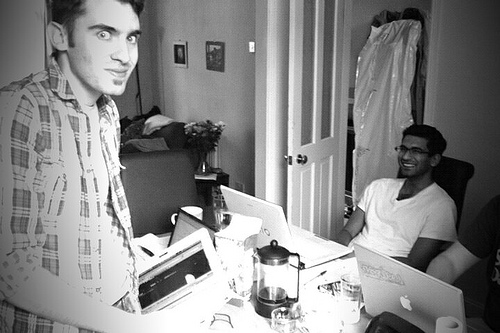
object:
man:
[0, 0, 184, 333]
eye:
[97, 30, 112, 40]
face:
[66, 0, 141, 97]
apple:
[399, 294, 412, 312]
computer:
[353, 242, 466, 333]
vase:
[196, 159, 212, 176]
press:
[132, 228, 224, 314]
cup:
[340, 273, 363, 324]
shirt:
[347, 177, 458, 258]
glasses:
[394, 146, 430, 155]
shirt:
[0, 59, 136, 333]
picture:
[205, 41, 224, 73]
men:
[333, 124, 461, 274]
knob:
[296, 154, 307, 166]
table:
[92, 230, 351, 332]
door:
[287, 0, 356, 240]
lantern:
[253, 239, 304, 318]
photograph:
[171, 41, 188, 69]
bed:
[119, 150, 210, 239]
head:
[43, 1, 164, 96]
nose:
[111, 43, 131, 64]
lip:
[104, 68, 128, 78]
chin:
[85, 76, 128, 96]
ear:
[47, 21, 69, 51]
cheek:
[69, 35, 111, 86]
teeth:
[403, 163, 415, 167]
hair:
[47, 1, 145, 60]